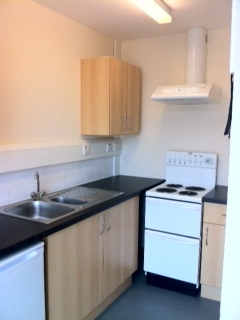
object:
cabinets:
[80, 56, 127, 136]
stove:
[143, 149, 220, 298]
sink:
[0, 198, 82, 225]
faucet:
[30, 171, 45, 201]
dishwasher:
[0, 242, 47, 319]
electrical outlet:
[106, 143, 114, 155]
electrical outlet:
[83, 144, 91, 156]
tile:
[10, 186, 26, 202]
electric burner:
[154, 187, 178, 194]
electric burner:
[178, 191, 198, 198]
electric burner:
[164, 182, 184, 189]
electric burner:
[184, 185, 204, 192]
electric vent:
[150, 27, 222, 104]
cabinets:
[47, 215, 105, 320]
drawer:
[202, 201, 228, 225]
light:
[133, 0, 173, 25]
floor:
[91, 246, 221, 319]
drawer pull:
[220, 212, 226, 218]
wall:
[0, 2, 115, 204]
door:
[109, 58, 127, 135]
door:
[126, 64, 140, 136]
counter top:
[0, 174, 165, 258]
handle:
[122, 115, 128, 132]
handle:
[128, 119, 133, 133]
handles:
[99, 215, 105, 235]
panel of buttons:
[198, 159, 203, 164]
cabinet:
[199, 184, 228, 303]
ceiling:
[32, 2, 232, 38]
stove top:
[144, 179, 214, 203]